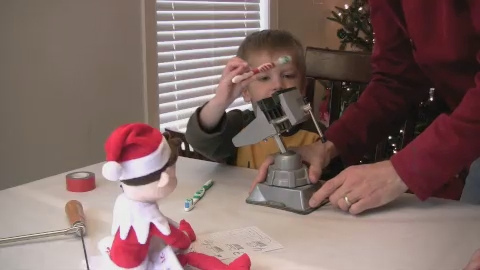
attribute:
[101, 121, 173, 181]
hat — red, white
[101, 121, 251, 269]
elf doll — plush, stuffed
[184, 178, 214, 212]
toothbrush — green, white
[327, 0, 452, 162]
christmas tree — lit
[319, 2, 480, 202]
blouse — dark red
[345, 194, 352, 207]
wedding band — gold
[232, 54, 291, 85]
toothbrush — red, green, white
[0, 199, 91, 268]
hack saw — wooden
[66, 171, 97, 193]
roll of tape — red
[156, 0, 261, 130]
blinds — venetian, white